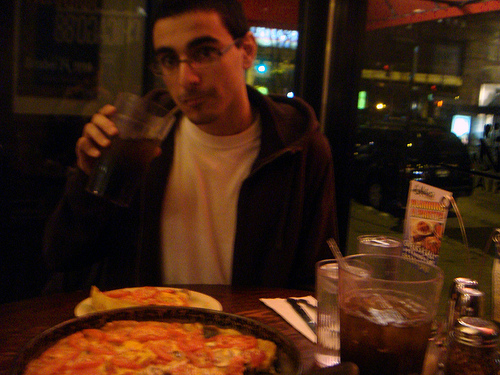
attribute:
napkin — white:
[257, 290, 320, 344]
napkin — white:
[260, 294, 317, 344]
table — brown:
[0, 287, 318, 374]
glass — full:
[310, 256, 350, 366]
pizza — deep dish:
[10, 318, 300, 374]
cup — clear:
[87, 88, 182, 213]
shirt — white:
[162, 114, 259, 284]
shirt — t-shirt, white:
[171, 107, 236, 292]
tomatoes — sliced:
[80, 300, 254, 375]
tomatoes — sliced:
[94, 314, 190, 359]